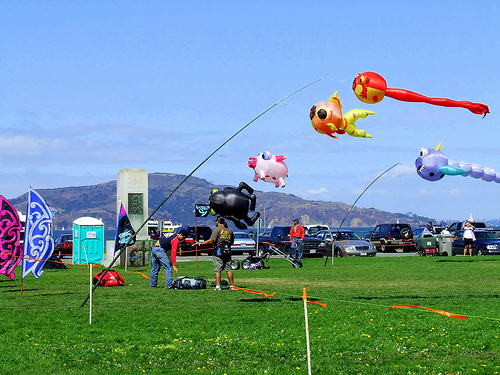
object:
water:
[342, 226, 373, 236]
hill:
[12, 172, 412, 236]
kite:
[308, 91, 375, 141]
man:
[149, 228, 189, 289]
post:
[300, 287, 315, 374]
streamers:
[390, 303, 468, 321]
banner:
[373, 159, 403, 182]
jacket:
[158, 231, 177, 250]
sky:
[0, 0, 499, 225]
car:
[313, 230, 377, 257]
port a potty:
[72, 217, 105, 266]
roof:
[69, 217, 106, 225]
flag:
[231, 285, 276, 298]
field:
[0, 253, 499, 374]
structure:
[116, 166, 148, 241]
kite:
[247, 150, 289, 188]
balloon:
[413, 145, 499, 183]